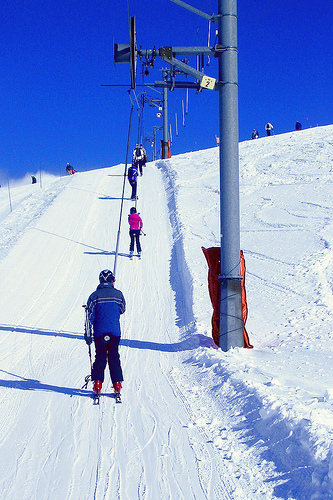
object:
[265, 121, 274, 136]
people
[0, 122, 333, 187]
hill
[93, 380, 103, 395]
boot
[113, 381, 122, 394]
boot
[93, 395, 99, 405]
ski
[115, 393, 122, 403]
ski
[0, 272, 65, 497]
snow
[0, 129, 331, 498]
tracks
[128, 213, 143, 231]
jacket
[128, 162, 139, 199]
person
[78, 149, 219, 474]
hill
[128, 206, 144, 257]
person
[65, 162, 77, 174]
person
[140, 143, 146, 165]
person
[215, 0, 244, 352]
poles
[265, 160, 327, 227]
snow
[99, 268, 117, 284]
helmet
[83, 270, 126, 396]
people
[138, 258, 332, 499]
snow bank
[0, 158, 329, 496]
lift trail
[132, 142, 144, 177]
person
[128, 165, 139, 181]
jacket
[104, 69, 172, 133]
ski tow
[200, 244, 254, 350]
pad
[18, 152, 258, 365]
snow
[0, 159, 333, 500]
ground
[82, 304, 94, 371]
ski poles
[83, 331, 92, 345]
hands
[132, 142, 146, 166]
lift